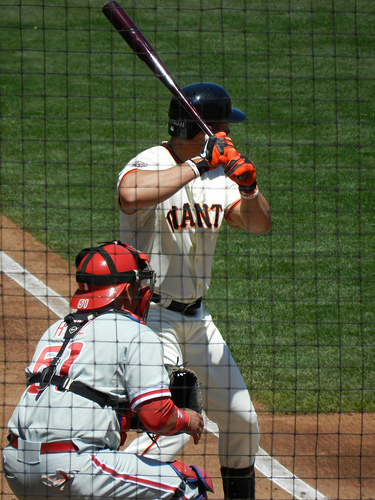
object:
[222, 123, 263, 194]
gloves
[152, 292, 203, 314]
belt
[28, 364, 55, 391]
box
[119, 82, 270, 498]
batter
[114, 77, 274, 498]
man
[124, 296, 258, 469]
pants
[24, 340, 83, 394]
number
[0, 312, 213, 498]
jersey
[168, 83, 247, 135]
helmet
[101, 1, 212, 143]
bat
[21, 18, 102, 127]
grass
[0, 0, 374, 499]
line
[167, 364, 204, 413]
mitt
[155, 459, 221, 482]
shinguard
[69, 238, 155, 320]
mask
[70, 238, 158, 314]
helmet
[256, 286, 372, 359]
grass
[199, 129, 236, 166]
gloves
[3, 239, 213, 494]
catcher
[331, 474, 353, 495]
dirt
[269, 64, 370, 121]
grass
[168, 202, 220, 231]
logo